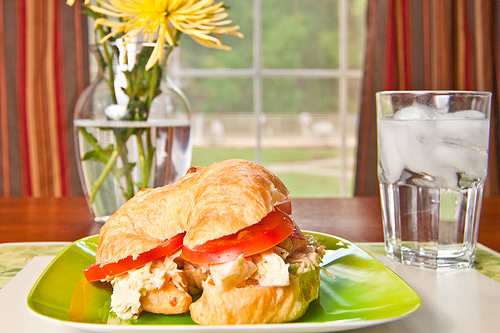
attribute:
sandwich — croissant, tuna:
[103, 175, 314, 314]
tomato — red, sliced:
[185, 211, 303, 261]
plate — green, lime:
[59, 233, 415, 332]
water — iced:
[388, 119, 481, 249]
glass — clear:
[371, 78, 483, 265]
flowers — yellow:
[94, 1, 235, 54]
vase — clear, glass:
[66, 50, 197, 212]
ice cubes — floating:
[385, 109, 479, 182]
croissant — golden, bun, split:
[118, 171, 261, 237]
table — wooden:
[2, 189, 472, 332]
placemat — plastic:
[1, 235, 499, 329]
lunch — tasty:
[83, 190, 306, 325]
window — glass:
[111, 1, 366, 190]